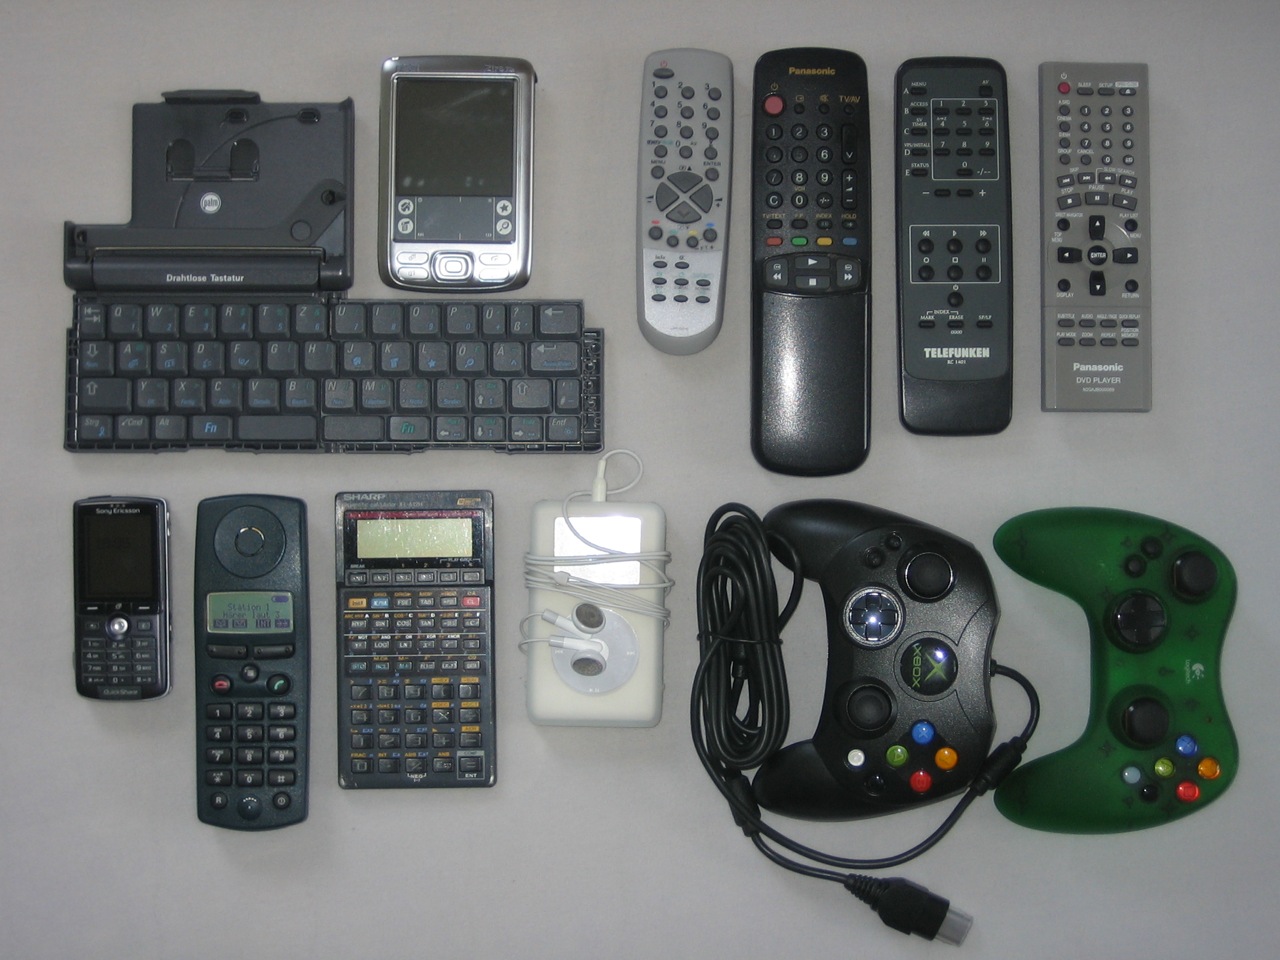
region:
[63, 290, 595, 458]
Black computer keyboard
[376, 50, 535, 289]
Silver cell phone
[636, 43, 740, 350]
Silver remote control with grey buttons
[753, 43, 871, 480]
Black remote control on top of desk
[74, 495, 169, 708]
Small silver and black cell phone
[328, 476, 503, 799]
Dark grey calculator on desk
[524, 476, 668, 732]
White MP3 player on desk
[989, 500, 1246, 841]
Green game controller on top of desk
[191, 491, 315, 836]
Black phone on top of desk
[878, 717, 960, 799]
Buttons on a black game remote control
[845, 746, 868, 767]
A white button on a black remote control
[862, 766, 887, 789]
A black button on a black surface of a remote control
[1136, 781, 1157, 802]
A black button on the surface of a green remote control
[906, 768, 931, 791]
A red button on the surface of a black remote control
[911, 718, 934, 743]
A blue button on the surface of a black remote control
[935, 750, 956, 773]
An orange button towards the right edge of remote control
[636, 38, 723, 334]
electronic device on white table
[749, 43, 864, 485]
electronic device on white table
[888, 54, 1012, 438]
electronic device on white table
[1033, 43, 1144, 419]
electronic device on white table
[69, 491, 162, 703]
electronic device on white table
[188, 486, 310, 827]
electronic device on white table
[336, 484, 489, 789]
electronic device on white table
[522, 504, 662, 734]
electronic device on white table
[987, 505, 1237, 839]
electronic device on white table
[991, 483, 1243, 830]
green game controller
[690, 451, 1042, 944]
black cord attached to black game controller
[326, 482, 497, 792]
A control of an electronic device.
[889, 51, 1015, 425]
A control of an electronic device.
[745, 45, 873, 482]
A control of an electronic device.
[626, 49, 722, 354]
A control of an electronic device.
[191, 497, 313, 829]
A control of an electronic device.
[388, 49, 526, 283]
A control of an electronic device.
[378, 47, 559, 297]
silver and black cell phone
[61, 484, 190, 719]
silver and black cell phone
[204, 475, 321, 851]
large black cell phone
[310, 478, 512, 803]
black calculator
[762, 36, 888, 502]
black colored remote control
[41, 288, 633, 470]
black colored key board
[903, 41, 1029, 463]
black colored remote control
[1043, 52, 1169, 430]
black and gray colored remote control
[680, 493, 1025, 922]
black colored video game control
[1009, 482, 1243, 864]
green colored video game control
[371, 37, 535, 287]
silver and black colored cell phone on gray table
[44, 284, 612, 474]
white and black colored keyboard on gray table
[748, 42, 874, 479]
the remote is black in color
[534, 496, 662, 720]
the ipod is turned on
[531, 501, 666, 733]
the ipod is white in color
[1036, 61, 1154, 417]
gray remote next to black remote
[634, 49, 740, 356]
gray remote next to black remote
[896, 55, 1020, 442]
black remotenext to gray remote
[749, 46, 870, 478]
black remotenext to gray remote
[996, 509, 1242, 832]
green remote next to black remote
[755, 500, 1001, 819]
black remote next to green remote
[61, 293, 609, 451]
keyboard on top of white surface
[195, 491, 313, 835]
phone is next to phone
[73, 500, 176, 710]
phone is next to phone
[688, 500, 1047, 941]
black cord next to remote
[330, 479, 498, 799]
a scientific function calculator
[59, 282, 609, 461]
a black keyboard with white letters